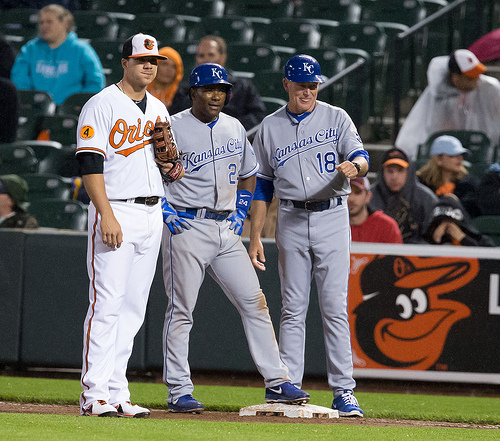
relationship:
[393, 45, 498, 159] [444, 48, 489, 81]
fan wearing a hat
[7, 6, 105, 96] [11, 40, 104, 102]
woman wearing a hoodie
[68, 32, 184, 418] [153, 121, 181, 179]
baseball player holding mitt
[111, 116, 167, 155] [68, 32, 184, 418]
logo on baseball player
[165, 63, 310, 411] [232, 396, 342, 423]
runner standing on base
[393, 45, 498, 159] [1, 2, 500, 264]
fan sitting in stands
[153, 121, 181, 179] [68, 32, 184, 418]
mitt on baseball player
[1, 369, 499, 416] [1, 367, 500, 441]
foul territory on field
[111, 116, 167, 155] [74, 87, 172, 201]
logo on jersey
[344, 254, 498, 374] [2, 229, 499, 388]
logo on wall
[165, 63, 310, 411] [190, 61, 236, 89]
runner wearing a helmet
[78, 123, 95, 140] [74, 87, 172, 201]
number on sleeve of jersey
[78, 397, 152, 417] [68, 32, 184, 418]
shoes worn by baseball player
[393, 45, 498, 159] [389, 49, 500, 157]
fan wearing a poncho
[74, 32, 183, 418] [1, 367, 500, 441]
baseball player are standing on field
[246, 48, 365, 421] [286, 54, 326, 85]
coach wearing a helmet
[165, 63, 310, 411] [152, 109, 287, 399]
runner wearing a uniform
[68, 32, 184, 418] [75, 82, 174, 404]
baseball player wearing a uniform